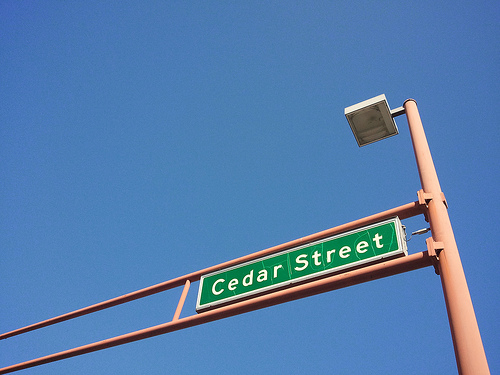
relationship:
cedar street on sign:
[208, 222, 389, 294] [193, 213, 412, 314]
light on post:
[336, 92, 403, 152] [396, 90, 480, 330]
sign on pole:
[193, 213, 412, 314] [396, 90, 480, 330]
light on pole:
[336, 92, 403, 152] [396, 90, 480, 330]